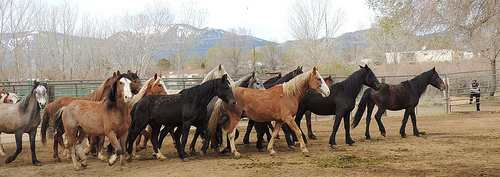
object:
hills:
[0, 24, 499, 79]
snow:
[126, 23, 200, 37]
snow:
[162, 71, 199, 85]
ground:
[0, 94, 500, 176]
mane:
[408, 71, 432, 97]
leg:
[399, 105, 414, 138]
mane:
[130, 78, 153, 107]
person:
[469, 82, 481, 111]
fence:
[444, 68, 499, 114]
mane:
[105, 75, 136, 111]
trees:
[289, 0, 343, 73]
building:
[384, 41, 482, 64]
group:
[0, 63, 445, 171]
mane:
[229, 73, 253, 87]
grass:
[440, 111, 499, 167]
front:
[351, 66, 447, 138]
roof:
[378, 39, 470, 53]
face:
[309, 75, 331, 97]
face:
[117, 76, 135, 103]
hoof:
[301, 151, 310, 157]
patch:
[339, 155, 356, 161]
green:
[227, 147, 408, 171]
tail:
[350, 88, 372, 129]